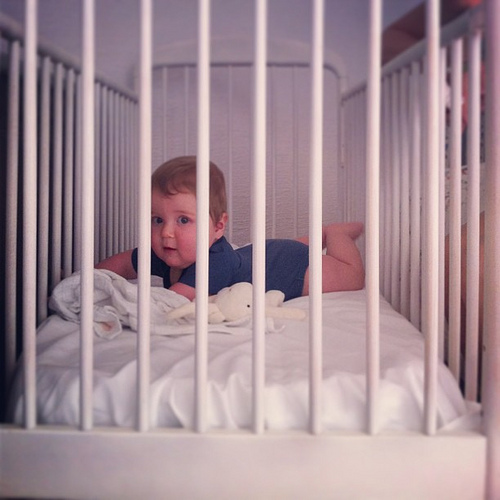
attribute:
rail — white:
[22, 0, 39, 429]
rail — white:
[367, 0, 385, 433]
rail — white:
[309, 0, 324, 432]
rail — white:
[420, 1, 439, 436]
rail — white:
[249, 0, 267, 434]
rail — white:
[192, 0, 211, 431]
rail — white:
[134, 0, 151, 430]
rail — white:
[3, 39, 20, 393]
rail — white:
[37, 54, 48, 331]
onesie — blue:
[130, 234, 308, 301]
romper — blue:
[130, 233, 310, 303]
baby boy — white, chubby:
[94, 152, 364, 303]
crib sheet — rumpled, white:
[7, 272, 482, 434]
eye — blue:
[152, 214, 165, 224]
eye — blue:
[176, 214, 193, 224]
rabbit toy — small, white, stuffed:
[164, 280, 309, 323]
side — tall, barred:
[1, 12, 141, 420]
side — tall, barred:
[2, 2, 482, 498]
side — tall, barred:
[342, 2, 484, 401]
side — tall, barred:
[133, 29, 344, 248]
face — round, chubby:
[151, 186, 196, 268]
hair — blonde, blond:
[150, 156, 228, 225]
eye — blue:
[152, 215, 165, 225]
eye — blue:
[173, 214, 192, 224]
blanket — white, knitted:
[45, 265, 288, 342]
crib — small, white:
[2, 2, 477, 498]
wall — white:
[2, 2, 426, 323]